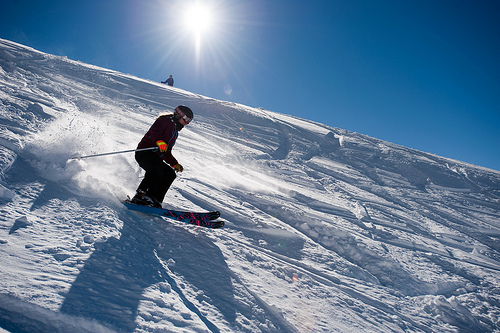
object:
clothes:
[133, 114, 184, 204]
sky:
[1, 0, 497, 173]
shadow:
[59, 209, 244, 333]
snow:
[0, 37, 499, 331]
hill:
[0, 40, 499, 333]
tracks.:
[368, 233, 498, 271]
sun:
[161, 0, 221, 41]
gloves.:
[171, 162, 187, 173]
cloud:
[11, 106, 133, 194]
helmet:
[173, 104, 196, 125]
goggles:
[178, 112, 196, 124]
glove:
[154, 138, 172, 153]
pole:
[70, 144, 159, 160]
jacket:
[132, 114, 181, 164]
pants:
[133, 151, 179, 201]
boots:
[132, 192, 164, 208]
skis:
[126, 203, 224, 228]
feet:
[133, 193, 164, 208]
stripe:
[156, 142, 166, 146]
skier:
[160, 73, 176, 87]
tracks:
[118, 201, 222, 331]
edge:
[0, 40, 499, 174]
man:
[128, 102, 200, 209]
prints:
[219, 235, 431, 333]